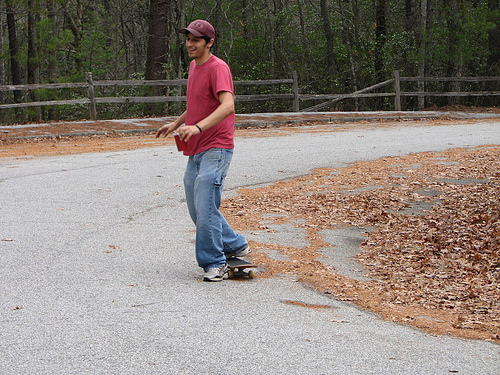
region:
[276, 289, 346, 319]
pink spot on the ground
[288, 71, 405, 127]
broken post in fence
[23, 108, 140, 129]
white lines in front of the fence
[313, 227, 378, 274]
bare spots on the sidewalk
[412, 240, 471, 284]
pile of gold leaves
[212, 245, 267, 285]
black skate board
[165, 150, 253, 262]
pair of over sized blue jeans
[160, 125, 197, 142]
cigarette in man's hand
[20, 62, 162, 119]
large brown wooden fence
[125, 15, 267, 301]
man skating on the street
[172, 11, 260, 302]
a young man riding a skateboard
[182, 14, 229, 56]
a man wearing a red hat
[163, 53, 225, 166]
a man wearing a red shirt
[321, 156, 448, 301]
brown leaves on the ground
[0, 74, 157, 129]
a wood fence with post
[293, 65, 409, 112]
a piece of the fence down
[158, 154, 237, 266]
a man wearing blue jeans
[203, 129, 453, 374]
a curve in the pavement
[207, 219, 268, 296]
a man with one foot on a skateboard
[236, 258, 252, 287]
part of a wheel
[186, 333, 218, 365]
part of a roads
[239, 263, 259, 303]
part of a wheel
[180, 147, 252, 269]
A pair of blue jeans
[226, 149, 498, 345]
Many leaves on the ground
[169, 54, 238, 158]
A red colored shirt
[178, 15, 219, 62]
Hat on man's head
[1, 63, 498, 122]
A wooden fence in the background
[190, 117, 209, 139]
Black bracelet around a wrist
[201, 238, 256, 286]
A pair of sneakers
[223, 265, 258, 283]
Wheels on a skateboard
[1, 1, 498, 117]
Trees behind the fence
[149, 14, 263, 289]
Man riding a skateboard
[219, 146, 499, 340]
dead brown leaves on ground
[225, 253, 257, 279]
black skateboard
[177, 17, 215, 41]
maroon baseball cap on head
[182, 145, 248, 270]
pair of blue jeans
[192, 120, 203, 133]
black bracelet on wrist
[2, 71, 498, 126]
corral fence along side of road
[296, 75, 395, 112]
broken log on corral fence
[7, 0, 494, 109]
green leaves on trees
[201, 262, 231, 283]
white sneaker with black trim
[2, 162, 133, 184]
tire track on road